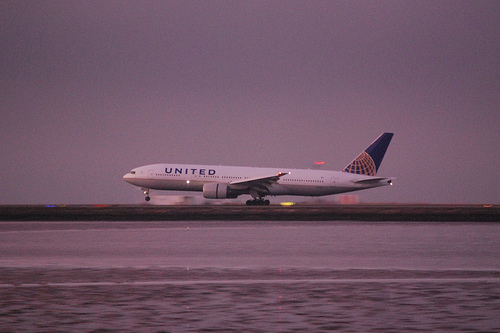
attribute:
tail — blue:
[343, 131, 394, 173]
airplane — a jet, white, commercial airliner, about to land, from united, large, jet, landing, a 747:
[123, 132, 394, 205]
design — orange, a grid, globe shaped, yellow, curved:
[344, 150, 377, 174]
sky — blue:
[0, 0, 500, 205]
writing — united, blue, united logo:
[165, 165, 217, 176]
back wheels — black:
[245, 200, 270, 207]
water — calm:
[0, 220, 500, 332]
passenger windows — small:
[149, 172, 251, 180]